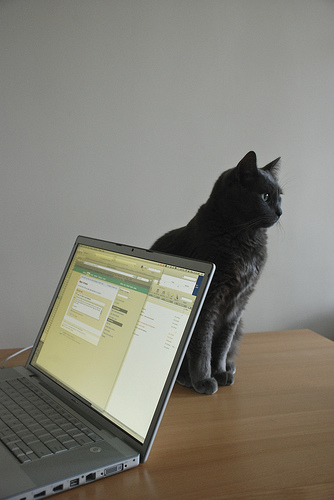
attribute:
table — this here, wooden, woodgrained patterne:
[2, 327, 332, 499]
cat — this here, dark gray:
[145, 149, 287, 397]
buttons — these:
[2, 375, 107, 480]